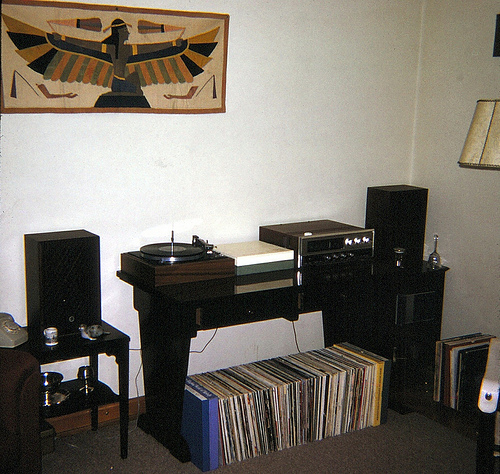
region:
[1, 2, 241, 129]
Picture of a man who looks like a bird.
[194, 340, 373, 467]
Collection of old record albums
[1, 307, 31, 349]
Rotary dial phone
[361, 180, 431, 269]
Stereo speaker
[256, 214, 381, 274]
Stereo console with silver knobs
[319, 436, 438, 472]
Section of brown carpet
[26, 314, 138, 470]
A small table with various items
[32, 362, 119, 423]
Silver items on bottom shelf of table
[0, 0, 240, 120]
Picture with a wooden frame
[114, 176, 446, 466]
Black desk with stereo components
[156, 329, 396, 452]
vinyls line the floor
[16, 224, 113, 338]
speaker is jet black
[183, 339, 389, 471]
A collection of record albums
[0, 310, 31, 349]
Beige rotary telephone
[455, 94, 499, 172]
Corner of a beige lampshade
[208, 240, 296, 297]
Box that is green, white , black and beige striped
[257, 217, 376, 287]
Stereo component/reciever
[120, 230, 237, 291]
A turntable with a record on it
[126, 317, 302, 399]
Wires that are against a wall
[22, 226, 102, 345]
Black stereo speaker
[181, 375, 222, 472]
Purple record album cover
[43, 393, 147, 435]
Brown wooden baseboard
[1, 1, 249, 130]
picture hanging on wall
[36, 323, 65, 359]
little white cup sitting on table top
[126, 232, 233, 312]
black turn table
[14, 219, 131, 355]
black stereo speaker on table top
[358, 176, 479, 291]
black stereo speaker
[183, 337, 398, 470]
albums in covers stacked on floor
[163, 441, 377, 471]
gray carpet on floor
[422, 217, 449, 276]
clear glass bell on table top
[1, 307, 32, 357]
gray rotatory phone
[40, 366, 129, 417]
solver containers on bottom shelf on table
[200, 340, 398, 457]
record collection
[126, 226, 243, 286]
record player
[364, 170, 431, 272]
the speaker on the right side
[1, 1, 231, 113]
A brown framed wall hanging with wings.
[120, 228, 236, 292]
A brown record player with record on top.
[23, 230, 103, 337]
Brown and black speaker to the left of a record player.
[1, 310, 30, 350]
A tan rotary phone.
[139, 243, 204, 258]
Black record on a record player.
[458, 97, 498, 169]
A cream colored lamp shade.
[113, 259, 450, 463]
A black desk with music equipment on top.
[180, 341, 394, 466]
Row of records under a table.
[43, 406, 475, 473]
Carpeted dark grey floor.